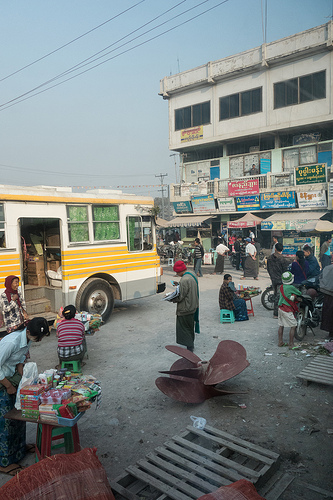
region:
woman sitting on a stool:
[204, 258, 257, 338]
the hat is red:
[167, 254, 187, 279]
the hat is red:
[160, 247, 204, 284]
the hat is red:
[170, 259, 188, 274]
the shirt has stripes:
[63, 327, 75, 340]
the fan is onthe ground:
[165, 343, 238, 402]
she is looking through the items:
[18, 321, 74, 410]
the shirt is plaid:
[3, 303, 19, 317]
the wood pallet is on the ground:
[138, 445, 168, 465]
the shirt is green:
[285, 287, 291, 297]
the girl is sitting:
[218, 273, 243, 319]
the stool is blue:
[221, 311, 231, 321]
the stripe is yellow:
[71, 249, 84, 257]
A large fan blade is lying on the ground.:
[138, 336, 255, 414]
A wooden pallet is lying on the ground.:
[100, 411, 284, 499]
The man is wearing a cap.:
[157, 254, 207, 360]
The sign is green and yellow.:
[292, 161, 329, 185]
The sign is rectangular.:
[292, 160, 327, 184]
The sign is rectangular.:
[256, 188, 297, 210]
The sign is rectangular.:
[295, 188, 327, 209]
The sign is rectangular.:
[225, 177, 260, 196]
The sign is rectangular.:
[233, 193, 261, 212]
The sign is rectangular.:
[188, 191, 217, 214]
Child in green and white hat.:
[272, 271, 302, 348]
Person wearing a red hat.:
[165, 259, 202, 350]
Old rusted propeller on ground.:
[151, 333, 252, 405]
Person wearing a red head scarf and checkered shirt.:
[0, 274, 28, 333]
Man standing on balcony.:
[240, 162, 265, 184]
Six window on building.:
[167, 66, 330, 134]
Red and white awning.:
[227, 212, 262, 230]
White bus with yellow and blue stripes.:
[0, 182, 165, 323]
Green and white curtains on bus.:
[68, 205, 139, 251]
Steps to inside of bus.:
[24, 284, 58, 324]